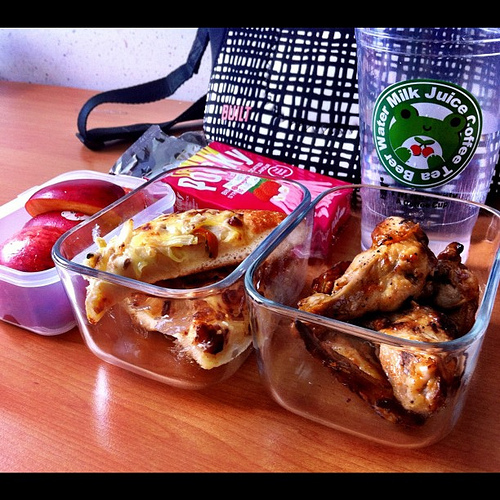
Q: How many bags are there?
A: One.